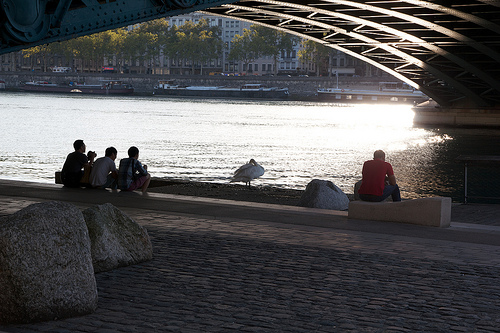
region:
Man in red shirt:
[357, 148, 400, 200]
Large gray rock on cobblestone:
[5, 197, 99, 321]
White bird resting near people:
[233, 158, 263, 188]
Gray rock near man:
[304, 178, 348, 210]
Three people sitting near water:
[54, 140, 150, 192]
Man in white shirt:
[93, 147, 116, 189]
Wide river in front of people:
[4, 88, 497, 184]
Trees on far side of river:
[27, 15, 356, 79]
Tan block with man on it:
[348, 193, 453, 228]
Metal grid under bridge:
[233, 1, 498, 103]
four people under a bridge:
[55, 0, 422, 202]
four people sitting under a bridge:
[8, 12, 455, 211]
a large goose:
[221, 142, 276, 197]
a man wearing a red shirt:
[357, 133, 406, 212]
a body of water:
[9, 79, 383, 139]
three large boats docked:
[4, 72, 404, 105]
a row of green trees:
[87, 34, 304, 78]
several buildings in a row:
[107, 32, 322, 81]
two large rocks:
[6, 204, 168, 318]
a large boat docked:
[148, 69, 296, 106]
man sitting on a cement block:
[355, 148, 400, 220]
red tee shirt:
[360, 155, 390, 197]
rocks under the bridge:
[2, 200, 154, 326]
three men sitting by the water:
[55, 136, 152, 192]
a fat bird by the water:
[232, 156, 268, 189]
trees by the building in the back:
[30, 23, 287, 76]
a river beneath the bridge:
[2, 86, 490, 203]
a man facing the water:
[352, 146, 402, 200]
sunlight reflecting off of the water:
[337, 92, 432, 164]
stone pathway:
[7, 188, 495, 330]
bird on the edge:
[233, 152, 268, 193]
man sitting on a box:
[365, 151, 401, 201]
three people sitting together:
[58, 145, 152, 193]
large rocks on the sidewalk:
[27, 182, 158, 291]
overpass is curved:
[255, 14, 460, 99]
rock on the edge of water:
[281, 162, 344, 223]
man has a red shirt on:
[381, 165, 399, 190]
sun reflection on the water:
[301, 96, 399, 146]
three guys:
[53, 145, 139, 193]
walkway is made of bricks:
[208, 220, 285, 316]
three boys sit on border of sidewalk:
[39, 133, 170, 211]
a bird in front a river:
[196, 96, 295, 196]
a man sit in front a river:
[345, 136, 416, 216]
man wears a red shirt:
[356, 145, 404, 202]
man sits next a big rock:
[291, 143, 409, 218]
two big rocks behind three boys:
[4, 132, 164, 330]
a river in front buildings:
[5, 14, 414, 186]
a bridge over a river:
[10, 3, 497, 139]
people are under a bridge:
[0, 3, 497, 230]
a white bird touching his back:
[222, 153, 269, 193]